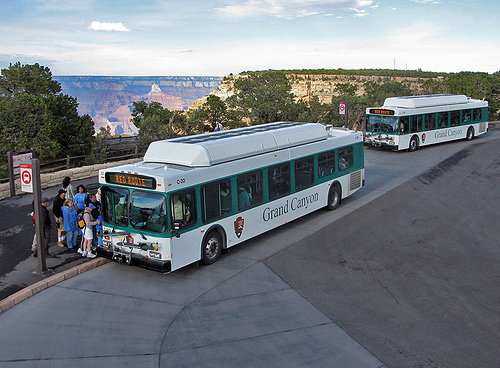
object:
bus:
[97, 121, 365, 276]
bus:
[364, 94, 489, 152]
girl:
[82, 204, 101, 258]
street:
[2, 128, 391, 297]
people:
[28, 173, 105, 257]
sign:
[234, 216, 245, 238]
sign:
[422, 133, 427, 143]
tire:
[202, 231, 223, 265]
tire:
[329, 184, 341, 210]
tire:
[409, 137, 417, 152]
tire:
[466, 125, 475, 141]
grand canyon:
[263, 192, 319, 222]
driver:
[161, 193, 190, 222]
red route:
[115, 175, 145, 187]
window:
[98, 184, 170, 236]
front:
[97, 170, 171, 276]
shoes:
[87, 251, 96, 259]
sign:
[105, 172, 157, 190]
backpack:
[76, 212, 85, 229]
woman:
[61, 199, 80, 251]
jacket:
[60, 206, 78, 232]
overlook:
[3, 128, 384, 179]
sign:
[20, 164, 33, 193]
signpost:
[28, 158, 48, 272]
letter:
[263, 207, 270, 222]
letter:
[271, 209, 275, 218]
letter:
[274, 208, 279, 218]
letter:
[279, 206, 283, 217]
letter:
[284, 200, 288, 214]